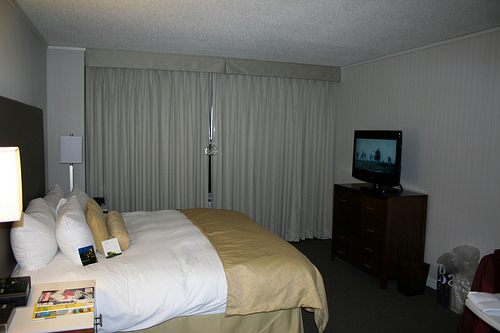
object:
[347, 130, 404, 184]
tv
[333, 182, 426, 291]
chest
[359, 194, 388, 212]
drawers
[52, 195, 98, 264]
pillows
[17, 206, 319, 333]
bed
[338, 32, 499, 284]
wall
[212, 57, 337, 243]
curtains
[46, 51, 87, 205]
wall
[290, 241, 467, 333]
floor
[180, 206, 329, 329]
cover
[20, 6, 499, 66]
ceiling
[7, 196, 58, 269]
pillow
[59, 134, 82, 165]
lamp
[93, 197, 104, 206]
table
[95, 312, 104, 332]
handle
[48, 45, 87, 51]
edge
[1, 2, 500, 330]
bedroom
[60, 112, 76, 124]
shade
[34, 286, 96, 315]
magazines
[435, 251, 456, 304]
bag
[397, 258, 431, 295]
trashcan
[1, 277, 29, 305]
clock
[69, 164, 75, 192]
column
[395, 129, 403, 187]
edge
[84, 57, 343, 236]
window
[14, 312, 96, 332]
surface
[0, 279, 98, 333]
cupboard